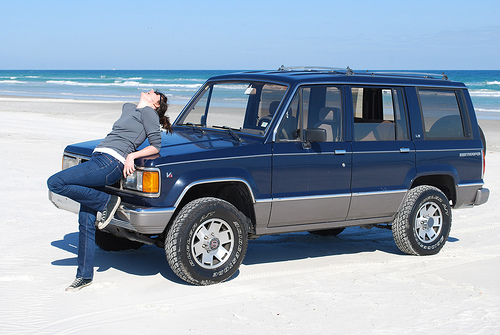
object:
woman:
[43, 90, 174, 293]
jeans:
[53, 150, 122, 279]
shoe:
[65, 275, 92, 295]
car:
[52, 65, 490, 284]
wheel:
[164, 197, 251, 285]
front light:
[142, 171, 164, 194]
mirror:
[298, 129, 328, 146]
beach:
[4, 97, 499, 329]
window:
[342, 82, 412, 143]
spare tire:
[426, 115, 488, 184]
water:
[3, 74, 100, 89]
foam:
[39, 80, 197, 89]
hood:
[94, 105, 163, 167]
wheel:
[397, 187, 450, 257]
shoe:
[91, 196, 125, 228]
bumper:
[42, 187, 176, 233]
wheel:
[96, 225, 145, 248]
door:
[264, 88, 356, 228]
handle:
[330, 146, 349, 155]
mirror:
[243, 82, 260, 93]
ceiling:
[210, 77, 467, 96]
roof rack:
[274, 59, 357, 76]